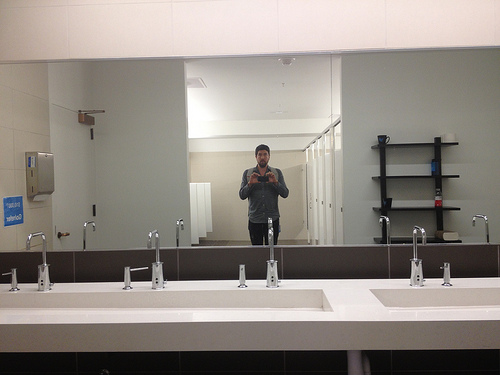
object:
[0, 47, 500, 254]
mirror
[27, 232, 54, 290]
faucet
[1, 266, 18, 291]
soap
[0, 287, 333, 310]
sink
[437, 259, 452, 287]
pipes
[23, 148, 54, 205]
napkins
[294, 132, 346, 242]
stalls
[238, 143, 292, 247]
man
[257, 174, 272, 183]
camera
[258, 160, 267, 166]
beard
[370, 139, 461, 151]
shelf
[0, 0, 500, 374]
bathroom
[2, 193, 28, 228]
sign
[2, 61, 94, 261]
wall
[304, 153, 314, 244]
door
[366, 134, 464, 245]
shef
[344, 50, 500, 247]
wall